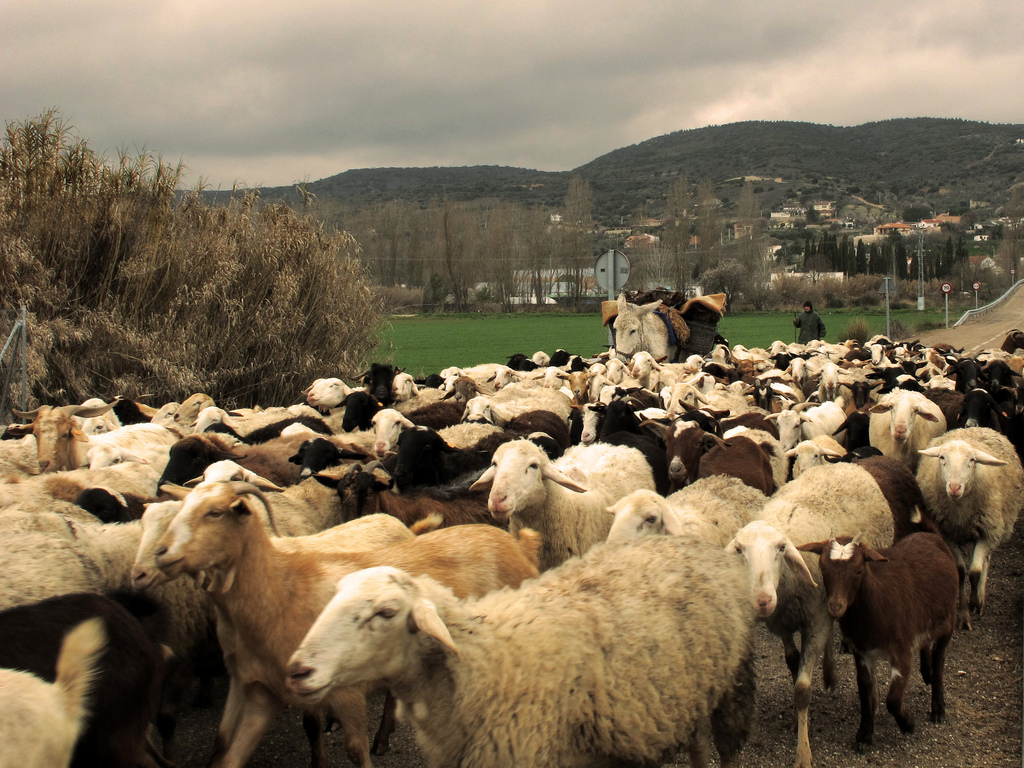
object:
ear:
[413, 600, 463, 666]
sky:
[0, 0, 1024, 188]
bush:
[0, 106, 394, 438]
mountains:
[169, 117, 1021, 277]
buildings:
[688, 198, 961, 288]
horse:
[600, 287, 728, 364]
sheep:
[640, 417, 777, 497]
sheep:
[287, 534, 756, 768]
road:
[673, 549, 1024, 768]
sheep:
[600, 474, 769, 550]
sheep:
[0, 592, 158, 768]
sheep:
[796, 532, 961, 755]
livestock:
[0, 287, 1024, 768]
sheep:
[0, 528, 102, 608]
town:
[507, 161, 1024, 404]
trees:
[241, 173, 781, 312]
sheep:
[917, 427, 1024, 617]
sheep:
[725, 462, 898, 768]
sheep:
[462, 389, 575, 429]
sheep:
[372, 408, 504, 456]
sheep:
[301, 378, 367, 413]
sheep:
[832, 412, 870, 451]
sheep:
[132, 481, 540, 768]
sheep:
[469, 440, 656, 574]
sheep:
[156, 431, 350, 488]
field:
[0, 313, 1024, 768]